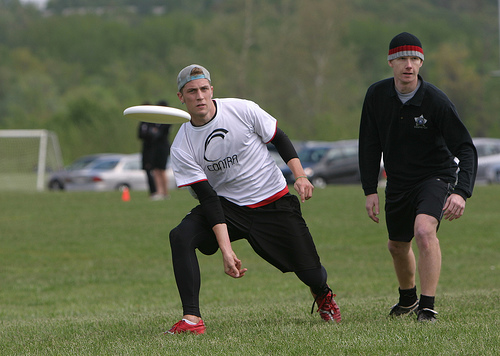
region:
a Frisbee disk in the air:
[122, 104, 192, 124]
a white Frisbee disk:
[122, 103, 191, 127]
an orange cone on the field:
[119, 184, 131, 202]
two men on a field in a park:
[167, 29, 478, 336]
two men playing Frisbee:
[7, 30, 494, 352]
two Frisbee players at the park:
[120, 30, 481, 337]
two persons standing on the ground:
[137, 97, 172, 203]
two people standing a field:
[134, 100, 172, 202]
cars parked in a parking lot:
[42, 138, 499, 193]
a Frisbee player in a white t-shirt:
[122, 63, 342, 336]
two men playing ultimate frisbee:
[111, 24, 485, 344]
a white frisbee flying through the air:
[119, 100, 196, 142]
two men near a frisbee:
[99, 28, 488, 208]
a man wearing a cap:
[383, 30, 430, 89]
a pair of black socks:
[391, 279, 448, 310]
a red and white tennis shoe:
[161, 319, 209, 338]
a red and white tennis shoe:
[307, 287, 347, 325]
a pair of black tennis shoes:
[383, 299, 440, 331]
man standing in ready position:
[355, 26, 475, 331]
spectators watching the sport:
[125, 90, 175, 200]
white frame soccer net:
[0, 120, 65, 197]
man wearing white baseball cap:
[166, 60, 221, 120]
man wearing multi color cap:
[380, 30, 430, 90]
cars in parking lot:
[42, 127, 494, 183]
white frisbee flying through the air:
[115, 95, 190, 130]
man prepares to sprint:
[350, 30, 475, 322]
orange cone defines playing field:
[117, 183, 133, 207]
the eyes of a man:
[165, 74, 227, 105]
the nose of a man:
[187, 78, 221, 108]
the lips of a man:
[187, 99, 221, 120]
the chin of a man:
[180, 103, 227, 131]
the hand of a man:
[214, 240, 265, 297]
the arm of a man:
[188, 157, 257, 246]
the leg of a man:
[153, 185, 250, 347]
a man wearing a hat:
[163, 60, 260, 125]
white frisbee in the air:
[118, 98, 194, 129]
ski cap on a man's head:
[382, 30, 425, 65]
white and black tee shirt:
[168, 91, 288, 206]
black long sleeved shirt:
[354, 71, 482, 203]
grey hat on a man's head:
[173, 62, 214, 91]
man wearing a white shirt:
[156, 57, 346, 335]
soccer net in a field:
[3, 125, 65, 198]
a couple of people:
[118, 11, 486, 342]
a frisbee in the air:
[114, 94, 205, 129]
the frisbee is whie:
[116, 85, 202, 136]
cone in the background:
[110, 175, 135, 208]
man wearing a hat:
[380, 30, 427, 67]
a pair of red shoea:
[154, 292, 370, 332]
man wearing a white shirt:
[145, 80, 297, 217]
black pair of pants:
[374, 158, 469, 250]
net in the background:
[0, 115, 79, 194]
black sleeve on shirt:
[189, 174, 234, 240]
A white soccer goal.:
[4, 129, 61, 194]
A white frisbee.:
[121, 103, 191, 129]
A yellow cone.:
[122, 189, 130, 204]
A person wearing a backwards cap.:
[157, 53, 344, 327]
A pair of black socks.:
[395, 283, 437, 308]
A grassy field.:
[7, 190, 497, 350]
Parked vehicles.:
[45, 140, 498, 195]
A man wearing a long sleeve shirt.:
[347, 29, 469, 331]